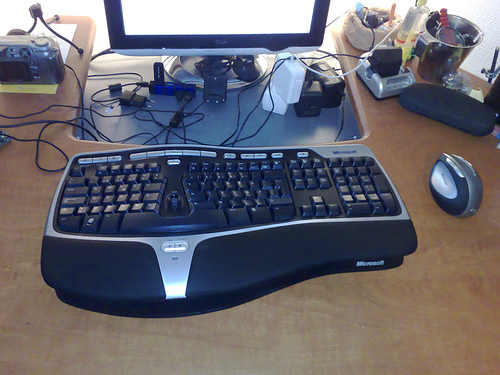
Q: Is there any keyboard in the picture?
A: Yes, there is a keyboard.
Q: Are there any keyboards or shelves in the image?
A: Yes, there is a keyboard.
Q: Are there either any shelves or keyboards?
A: Yes, there is a keyboard.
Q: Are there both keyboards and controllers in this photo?
A: No, there is a keyboard but no controllers.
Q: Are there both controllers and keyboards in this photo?
A: No, there is a keyboard but no controllers.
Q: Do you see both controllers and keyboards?
A: No, there is a keyboard but no controllers.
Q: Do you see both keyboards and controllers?
A: No, there is a keyboard but no controllers.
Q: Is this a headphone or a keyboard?
A: This is a keyboard.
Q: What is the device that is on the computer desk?
A: The device is a keyboard.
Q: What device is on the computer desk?
A: The device is a keyboard.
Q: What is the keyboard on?
A: The keyboard is on the computer desk.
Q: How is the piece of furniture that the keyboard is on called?
A: The piece of furniture is a computer desk.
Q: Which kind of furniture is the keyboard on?
A: The keyboard is on the computer desk.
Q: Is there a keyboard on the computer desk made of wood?
A: Yes, there is a keyboard on the computer desk.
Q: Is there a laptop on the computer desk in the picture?
A: No, there is a keyboard on the computer desk.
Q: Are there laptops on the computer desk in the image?
A: No, there is a keyboard on the computer desk.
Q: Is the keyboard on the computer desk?
A: Yes, the keyboard is on the computer desk.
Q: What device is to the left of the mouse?
A: The device is a keyboard.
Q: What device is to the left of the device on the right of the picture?
A: The device is a keyboard.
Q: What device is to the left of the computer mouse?
A: The device is a keyboard.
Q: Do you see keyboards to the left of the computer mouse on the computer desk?
A: Yes, there is a keyboard to the left of the computer mouse.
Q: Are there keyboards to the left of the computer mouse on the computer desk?
A: Yes, there is a keyboard to the left of the computer mouse.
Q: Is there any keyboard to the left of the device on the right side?
A: Yes, there is a keyboard to the left of the computer mouse.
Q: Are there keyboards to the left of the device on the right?
A: Yes, there is a keyboard to the left of the computer mouse.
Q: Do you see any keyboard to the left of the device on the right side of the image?
A: Yes, there is a keyboard to the left of the computer mouse.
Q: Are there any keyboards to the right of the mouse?
A: No, the keyboard is to the left of the mouse.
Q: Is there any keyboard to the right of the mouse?
A: No, the keyboard is to the left of the mouse.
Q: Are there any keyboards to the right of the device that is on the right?
A: No, the keyboard is to the left of the mouse.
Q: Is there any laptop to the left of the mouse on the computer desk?
A: No, there is a keyboard to the left of the computer mouse.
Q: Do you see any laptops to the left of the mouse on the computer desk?
A: No, there is a keyboard to the left of the computer mouse.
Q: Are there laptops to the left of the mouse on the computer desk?
A: No, there is a keyboard to the left of the computer mouse.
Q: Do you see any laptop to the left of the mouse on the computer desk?
A: No, there is a keyboard to the left of the computer mouse.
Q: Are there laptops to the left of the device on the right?
A: No, there is a keyboard to the left of the computer mouse.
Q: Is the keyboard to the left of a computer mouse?
A: Yes, the keyboard is to the left of a computer mouse.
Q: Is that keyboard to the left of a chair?
A: No, the keyboard is to the left of a computer mouse.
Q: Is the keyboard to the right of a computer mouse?
A: No, the keyboard is to the left of a computer mouse.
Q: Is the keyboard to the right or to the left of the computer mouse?
A: The keyboard is to the left of the computer mouse.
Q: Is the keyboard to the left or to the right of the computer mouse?
A: The keyboard is to the left of the computer mouse.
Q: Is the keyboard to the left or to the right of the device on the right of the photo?
A: The keyboard is to the left of the computer mouse.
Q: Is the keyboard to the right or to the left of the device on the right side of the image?
A: The keyboard is to the left of the computer mouse.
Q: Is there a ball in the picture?
A: No, there are no balls.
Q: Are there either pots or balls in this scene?
A: No, there are no balls or pots.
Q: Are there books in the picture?
A: No, there are no books.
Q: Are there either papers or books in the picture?
A: No, there are no books or papers.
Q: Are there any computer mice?
A: Yes, there is a computer mouse.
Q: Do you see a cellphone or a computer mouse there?
A: Yes, there is a computer mouse.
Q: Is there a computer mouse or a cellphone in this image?
A: Yes, there is a computer mouse.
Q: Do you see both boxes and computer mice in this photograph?
A: No, there is a computer mouse but no boxes.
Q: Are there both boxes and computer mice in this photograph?
A: No, there is a computer mouse but no boxes.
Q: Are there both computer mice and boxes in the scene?
A: No, there is a computer mouse but no boxes.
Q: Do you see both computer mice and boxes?
A: No, there is a computer mouse but no boxes.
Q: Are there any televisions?
A: No, there are no televisions.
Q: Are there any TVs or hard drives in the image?
A: No, there are no TVs or hard drives.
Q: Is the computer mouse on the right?
A: Yes, the computer mouse is on the right of the image.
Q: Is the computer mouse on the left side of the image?
A: No, the computer mouse is on the right of the image.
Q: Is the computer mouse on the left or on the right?
A: The computer mouse is on the right of the image.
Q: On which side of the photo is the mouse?
A: The mouse is on the right of the image.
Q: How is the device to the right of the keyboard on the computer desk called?
A: The device is a computer mouse.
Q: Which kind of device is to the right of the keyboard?
A: The device is a computer mouse.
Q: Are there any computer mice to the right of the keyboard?
A: Yes, there is a computer mouse to the right of the keyboard.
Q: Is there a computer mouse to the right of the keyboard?
A: Yes, there is a computer mouse to the right of the keyboard.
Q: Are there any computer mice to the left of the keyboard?
A: No, the computer mouse is to the right of the keyboard.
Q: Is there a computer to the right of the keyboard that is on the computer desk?
A: No, there is a computer mouse to the right of the keyboard.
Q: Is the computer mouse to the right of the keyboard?
A: Yes, the computer mouse is to the right of the keyboard.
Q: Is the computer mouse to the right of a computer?
A: No, the computer mouse is to the right of the keyboard.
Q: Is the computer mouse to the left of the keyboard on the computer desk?
A: No, the computer mouse is to the right of the keyboard.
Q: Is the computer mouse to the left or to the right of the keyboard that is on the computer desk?
A: The computer mouse is to the right of the keyboard.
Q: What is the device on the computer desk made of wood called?
A: The device is a computer mouse.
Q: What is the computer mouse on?
A: The computer mouse is on the computer desk.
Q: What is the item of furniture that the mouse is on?
A: The piece of furniture is a computer desk.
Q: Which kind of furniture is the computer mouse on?
A: The mouse is on the computer desk.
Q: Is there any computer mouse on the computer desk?
A: Yes, there is a computer mouse on the computer desk.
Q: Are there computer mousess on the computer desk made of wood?
A: No, there is a computer mouse on the computer desk.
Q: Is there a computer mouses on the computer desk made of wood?
A: No, there is a computer mouse on the computer desk.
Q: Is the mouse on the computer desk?
A: Yes, the mouse is on the computer desk.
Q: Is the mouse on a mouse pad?
A: No, the mouse is on the computer desk.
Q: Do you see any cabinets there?
A: No, there are no cabinets.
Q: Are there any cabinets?
A: No, there are no cabinets.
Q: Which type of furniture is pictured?
A: The furniture is a computer desk.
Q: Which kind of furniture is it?
A: The piece of furniture is a computer desk.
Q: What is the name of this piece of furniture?
A: This is a computer desk.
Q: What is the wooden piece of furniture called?
A: The piece of furniture is a computer desk.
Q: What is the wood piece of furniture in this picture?
A: The piece of furniture is a computer desk.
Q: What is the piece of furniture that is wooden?
A: The piece of furniture is a computer desk.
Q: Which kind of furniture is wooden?
A: The furniture is a computer desk.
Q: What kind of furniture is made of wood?
A: The furniture is a computer desk.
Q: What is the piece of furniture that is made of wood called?
A: The piece of furniture is a computer desk.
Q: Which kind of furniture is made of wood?
A: The furniture is a computer desk.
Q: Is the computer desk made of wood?
A: Yes, the computer desk is made of wood.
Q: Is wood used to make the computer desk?
A: Yes, the computer desk is made of wood.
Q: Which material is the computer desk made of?
A: The computer desk is made of wood.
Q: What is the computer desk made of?
A: The computer desk is made of wood.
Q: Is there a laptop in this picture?
A: No, there are no laptops.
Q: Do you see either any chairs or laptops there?
A: No, there are no laptops or chairs.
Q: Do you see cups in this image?
A: Yes, there is a cup.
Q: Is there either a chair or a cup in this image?
A: Yes, there is a cup.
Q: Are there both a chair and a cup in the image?
A: No, there is a cup but no chairs.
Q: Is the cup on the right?
A: Yes, the cup is on the right of the image.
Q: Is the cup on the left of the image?
A: No, the cup is on the right of the image.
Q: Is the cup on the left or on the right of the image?
A: The cup is on the right of the image.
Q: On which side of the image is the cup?
A: The cup is on the right of the image.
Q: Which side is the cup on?
A: The cup is on the right of the image.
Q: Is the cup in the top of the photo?
A: Yes, the cup is in the top of the image.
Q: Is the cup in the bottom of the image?
A: No, the cup is in the top of the image.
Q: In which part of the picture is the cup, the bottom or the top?
A: The cup is in the top of the image.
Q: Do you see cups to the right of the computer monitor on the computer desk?
A: Yes, there is a cup to the right of the computer monitor.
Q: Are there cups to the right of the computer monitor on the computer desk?
A: Yes, there is a cup to the right of the computer monitor.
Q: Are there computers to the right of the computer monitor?
A: No, there is a cup to the right of the computer monitor.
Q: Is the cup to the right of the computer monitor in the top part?
A: Yes, the cup is to the right of the computer monitor.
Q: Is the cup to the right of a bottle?
A: No, the cup is to the right of the computer monitor.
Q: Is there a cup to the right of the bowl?
A: Yes, there is a cup to the right of the bowl.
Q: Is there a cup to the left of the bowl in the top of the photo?
A: No, the cup is to the right of the bowl.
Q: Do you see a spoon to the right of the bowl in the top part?
A: No, there is a cup to the right of the bowl.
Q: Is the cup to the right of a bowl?
A: Yes, the cup is to the right of a bowl.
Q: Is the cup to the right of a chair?
A: No, the cup is to the right of a bowl.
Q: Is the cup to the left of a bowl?
A: No, the cup is to the right of a bowl.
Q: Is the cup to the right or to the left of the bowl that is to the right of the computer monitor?
A: The cup is to the right of the bowl.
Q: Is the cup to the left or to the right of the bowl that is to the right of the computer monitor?
A: The cup is to the right of the bowl.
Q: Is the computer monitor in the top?
A: Yes, the computer monitor is in the top of the image.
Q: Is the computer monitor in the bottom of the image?
A: No, the computer monitor is in the top of the image.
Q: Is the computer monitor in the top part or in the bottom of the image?
A: The computer monitor is in the top of the image.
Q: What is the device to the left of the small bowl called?
A: The device is a computer monitor.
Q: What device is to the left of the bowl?
A: The device is a computer monitor.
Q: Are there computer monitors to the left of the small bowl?
A: Yes, there is a computer monitor to the left of the bowl.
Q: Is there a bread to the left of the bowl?
A: No, there is a computer monitor to the left of the bowl.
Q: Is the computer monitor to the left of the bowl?
A: Yes, the computer monitor is to the left of the bowl.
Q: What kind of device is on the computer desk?
A: The device is a computer monitor.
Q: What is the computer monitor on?
A: The computer monitor is on the computer desk.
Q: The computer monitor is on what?
A: The computer monitor is on the computer desk.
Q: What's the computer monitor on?
A: The computer monitor is on the computer desk.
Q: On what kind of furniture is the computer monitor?
A: The computer monitor is on the computer desk.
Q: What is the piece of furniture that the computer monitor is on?
A: The piece of furniture is a computer desk.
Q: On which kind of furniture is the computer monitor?
A: The computer monitor is on the computer desk.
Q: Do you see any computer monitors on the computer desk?
A: Yes, there is a computer monitor on the computer desk.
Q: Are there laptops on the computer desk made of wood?
A: No, there is a computer monitor on the computer desk.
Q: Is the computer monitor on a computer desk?
A: Yes, the computer monitor is on a computer desk.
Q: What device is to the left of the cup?
A: The device is a computer monitor.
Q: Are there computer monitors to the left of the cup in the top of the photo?
A: Yes, there is a computer monitor to the left of the cup.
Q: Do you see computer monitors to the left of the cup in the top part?
A: Yes, there is a computer monitor to the left of the cup.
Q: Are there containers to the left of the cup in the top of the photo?
A: No, there is a computer monitor to the left of the cup.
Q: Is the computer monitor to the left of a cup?
A: Yes, the computer monitor is to the left of a cup.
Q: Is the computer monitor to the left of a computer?
A: No, the computer monitor is to the left of a cup.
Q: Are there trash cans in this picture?
A: No, there are no trash cans.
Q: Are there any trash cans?
A: No, there are no trash cans.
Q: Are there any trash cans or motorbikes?
A: No, there are no trash cans or motorbikes.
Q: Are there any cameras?
A: Yes, there is a camera.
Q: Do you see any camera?
A: Yes, there is a camera.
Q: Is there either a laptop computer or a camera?
A: Yes, there is a camera.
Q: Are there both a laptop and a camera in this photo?
A: No, there is a camera but no laptops.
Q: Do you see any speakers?
A: No, there are no speakers.